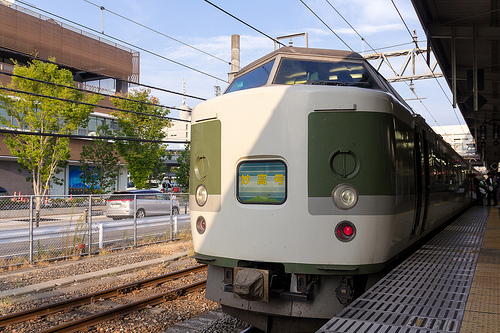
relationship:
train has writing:
[191, 46, 483, 318] [240, 172, 285, 186]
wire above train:
[392, 0, 466, 139] [191, 46, 483, 318]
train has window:
[191, 46, 483, 318] [272, 57, 381, 89]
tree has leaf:
[4, 52, 102, 226] [23, 102, 26, 103]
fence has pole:
[2, 192, 191, 267] [89, 195, 92, 255]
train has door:
[191, 46, 483, 318] [414, 132, 427, 236]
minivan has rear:
[106, 189, 179, 217] [106, 193, 132, 216]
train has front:
[191, 46, 483, 318] [191, 49, 387, 269]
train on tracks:
[191, 46, 483, 318] [238, 321, 254, 332]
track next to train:
[1, 263, 207, 329] [191, 46, 483, 318]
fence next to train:
[2, 192, 191, 267] [191, 46, 483, 318]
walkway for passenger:
[319, 198, 499, 330] [478, 175, 485, 204]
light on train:
[342, 224, 354, 234] [191, 46, 483, 318]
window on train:
[272, 57, 381, 89] [191, 46, 483, 318]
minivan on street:
[106, 189, 179, 217] [4, 204, 189, 241]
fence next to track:
[2, 192, 191, 267] [1, 263, 207, 329]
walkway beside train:
[319, 198, 499, 330] [191, 46, 483, 318]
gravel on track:
[2, 258, 220, 329] [1, 263, 207, 329]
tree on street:
[4, 52, 102, 226] [4, 204, 189, 241]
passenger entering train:
[478, 175, 485, 204] [191, 46, 483, 318]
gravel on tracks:
[1, 263, 207, 329] [2, 232, 378, 324]